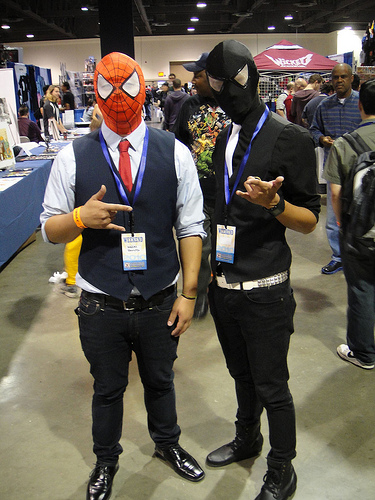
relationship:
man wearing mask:
[39, 50, 205, 499] [92, 51, 146, 133]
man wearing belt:
[205, 37, 321, 498] [213, 271, 289, 291]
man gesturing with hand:
[39, 50, 205, 499] [82, 184, 134, 235]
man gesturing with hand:
[205, 37, 321, 498] [234, 172, 284, 212]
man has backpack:
[322, 77, 373, 372] [337, 130, 373, 262]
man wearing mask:
[205, 37, 321, 498] [204, 40, 259, 122]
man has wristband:
[39, 50, 205, 499] [72, 206, 87, 233]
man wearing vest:
[205, 37, 321, 498] [210, 114, 292, 282]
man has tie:
[205, 37, 321, 498] [225, 121, 241, 178]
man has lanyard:
[39, 50, 205, 499] [99, 126, 151, 212]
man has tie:
[39, 50, 205, 499] [116, 140, 132, 192]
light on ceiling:
[190, 15, 198, 25] [1, 0, 366, 41]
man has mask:
[39, 50, 205, 499] [92, 51, 146, 133]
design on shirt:
[189, 105, 229, 178] [169, 94, 235, 186]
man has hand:
[39, 50, 205, 499] [82, 184, 134, 235]